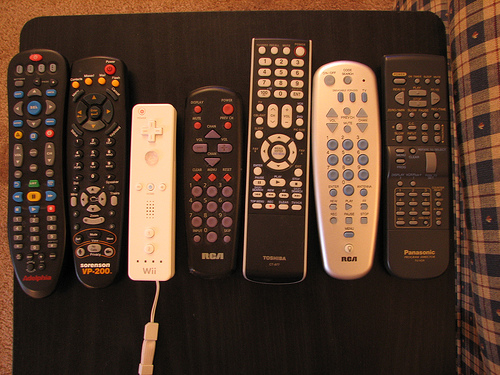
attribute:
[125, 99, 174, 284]
remote — wii remote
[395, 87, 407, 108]
button — gray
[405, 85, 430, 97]
button — gray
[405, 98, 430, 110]
button — gray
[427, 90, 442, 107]
button — gray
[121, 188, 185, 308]
controller — white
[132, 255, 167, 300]
lettering — gray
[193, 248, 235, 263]
lettering — gray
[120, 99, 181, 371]
gaming controller — white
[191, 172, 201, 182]
button — red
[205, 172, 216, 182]
button — red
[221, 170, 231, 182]
button — red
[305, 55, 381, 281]
remote — gray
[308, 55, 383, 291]
controller — black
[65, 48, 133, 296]
controller — black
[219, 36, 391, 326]
buttons — white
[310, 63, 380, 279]
controller — silver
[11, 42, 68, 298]
controller — long, black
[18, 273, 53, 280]
lettering — red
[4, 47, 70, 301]
controller — black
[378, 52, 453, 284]
controller — black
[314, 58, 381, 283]
controller — black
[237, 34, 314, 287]
controller — black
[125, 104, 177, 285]
controller — black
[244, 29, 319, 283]
controller — black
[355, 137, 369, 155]
button — gray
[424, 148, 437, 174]
button — gray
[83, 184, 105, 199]
button — gray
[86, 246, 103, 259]
button — gray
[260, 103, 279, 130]
button — gray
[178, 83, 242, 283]
controller — black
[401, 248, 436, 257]
lettering — white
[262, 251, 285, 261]
lettering — white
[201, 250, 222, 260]
lettering — white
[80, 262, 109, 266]
lettering — white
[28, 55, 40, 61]
lettering — white